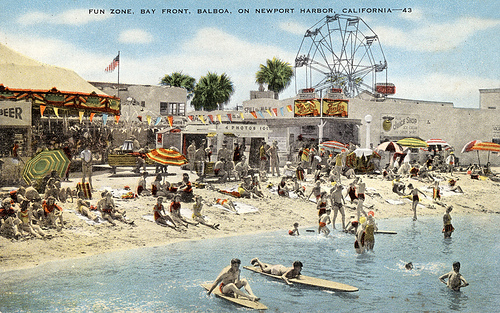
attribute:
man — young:
[250, 254, 304, 287]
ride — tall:
[293, 14, 395, 101]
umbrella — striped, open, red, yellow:
[147, 146, 187, 183]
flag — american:
[104, 55, 120, 72]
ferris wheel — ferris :
[293, 12, 394, 99]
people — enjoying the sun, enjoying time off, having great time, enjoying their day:
[134, 169, 196, 199]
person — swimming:
[404, 261, 421, 274]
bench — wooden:
[106, 152, 142, 176]